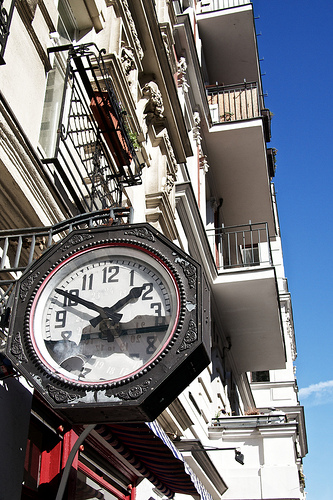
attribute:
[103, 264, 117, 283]
number — 12, black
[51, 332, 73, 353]
number — eight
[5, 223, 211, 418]
clock — black, white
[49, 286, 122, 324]
hand — big, large, black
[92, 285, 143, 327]
hand — small, black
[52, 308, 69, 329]
number — 9, black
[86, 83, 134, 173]
flower box — orange, terra cotta, brown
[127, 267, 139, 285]
number — 1, black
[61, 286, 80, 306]
number — 10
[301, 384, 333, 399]
cloud — white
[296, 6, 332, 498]
sky — blue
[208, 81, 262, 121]
railing — iron, black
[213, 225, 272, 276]
railing — iron, black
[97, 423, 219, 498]
awining — blue, white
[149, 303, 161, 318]
number — three, black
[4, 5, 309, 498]
building — tall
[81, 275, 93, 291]
number — 11